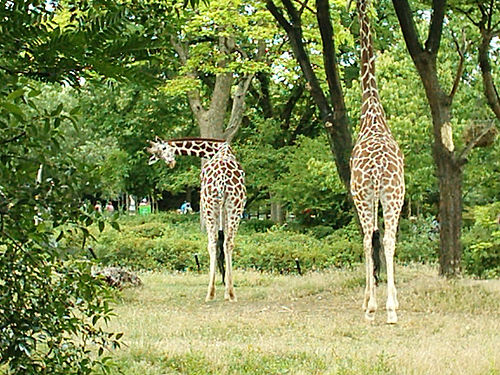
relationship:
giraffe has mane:
[141, 130, 250, 304] [163, 132, 228, 144]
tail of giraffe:
[209, 177, 229, 285] [139, 129, 268, 305]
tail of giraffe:
[365, 164, 386, 299] [324, 3, 414, 329]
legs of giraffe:
[191, 184, 217, 300] [141, 138, 262, 312]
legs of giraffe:
[219, 195, 249, 309] [141, 138, 262, 312]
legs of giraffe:
[349, 159, 380, 323] [338, 2, 413, 339]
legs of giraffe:
[380, 169, 407, 329] [338, 2, 413, 339]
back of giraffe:
[338, 183, 407, 221] [349, 122, 399, 148]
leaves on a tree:
[21, 250, 101, 328] [24, 84, 74, 234]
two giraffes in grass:
[142, 0, 406, 327] [77, 258, 487, 375]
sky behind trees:
[265, 53, 295, 113] [214, 115, 492, 210]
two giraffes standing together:
[142, 0, 406, 327] [232, 162, 352, 182]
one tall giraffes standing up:
[328, 55, 435, 350] [370, 275, 413, 373]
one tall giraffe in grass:
[337, 51, 424, 361] [137, 266, 491, 375]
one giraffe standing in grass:
[318, 131, 428, 301] [342, 307, 438, 343]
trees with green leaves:
[74, 55, 454, 215] [112, 101, 185, 116]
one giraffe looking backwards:
[130, 117, 256, 321] [154, 143, 180, 183]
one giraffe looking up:
[301, 53, 404, 233] [310, 99, 340, 105]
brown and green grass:
[211, 325, 254, 352] [82, 245, 492, 374]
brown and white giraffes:
[232, 175, 235, 184] [142, 62, 402, 302]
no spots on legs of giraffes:
[151, 176, 442, 305] [224, 212, 363, 218]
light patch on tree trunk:
[436, 123, 461, 155] [419, 177, 477, 268]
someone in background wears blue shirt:
[168, 189, 198, 223] [182, 205, 186, 209]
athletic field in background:
[35, 180, 195, 243] [48, 259, 222, 375]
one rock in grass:
[96, 267, 145, 295] [76, 263, 306, 373]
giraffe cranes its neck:
[141, 130, 250, 312] [158, 130, 226, 167]